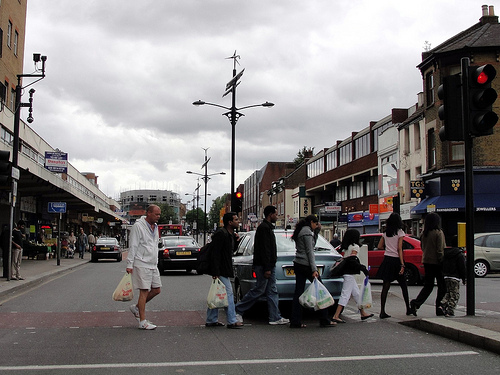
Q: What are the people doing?
A: Crossing the street.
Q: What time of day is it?
A: Daytime.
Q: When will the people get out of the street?
A: After they have reached the sidewalk.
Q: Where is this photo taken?
A: On a street.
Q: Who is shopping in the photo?
A: Men and women.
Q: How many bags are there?
A: Four.